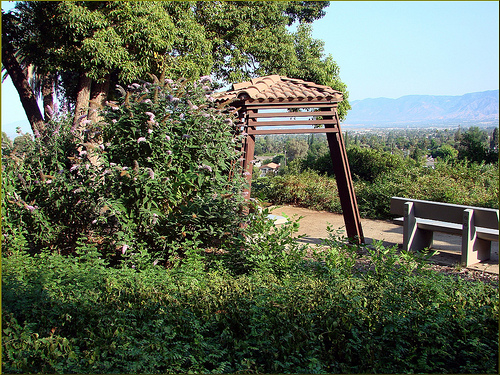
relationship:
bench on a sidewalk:
[379, 184, 479, 260] [278, 204, 483, 282]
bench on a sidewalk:
[390, 196, 500, 267] [276, 207, 458, 265]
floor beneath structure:
[266, 205, 329, 242] [221, 70, 378, 243]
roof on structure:
[207, 75, 342, 108] [232, 98, 376, 243]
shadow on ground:
[297, 234, 464, 267] [268, 199, 387, 234]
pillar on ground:
[330, 131, 372, 240] [271, 197, 391, 247]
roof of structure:
[207, 75, 342, 108] [226, 111, 371, 233]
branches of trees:
[72, 39, 125, 81] [15, 154, 271, 255]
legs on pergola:
[230, 140, 377, 244] [206, 75, 368, 247]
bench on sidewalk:
[390, 196, 500, 267] [266, 203, 499, 278]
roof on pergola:
[207, 75, 342, 108] [206, 75, 368, 247]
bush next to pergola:
[1, 77, 305, 263] [206, 75, 368, 247]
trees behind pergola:
[1, 1, 349, 166] [206, 75, 368, 247]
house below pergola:
[256, 151, 286, 171] [206, 75, 368, 247]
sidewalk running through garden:
[267, 201, 499, 286] [0, 1, 499, 373]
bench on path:
[390, 196, 500, 267] [268, 204, 498, 284]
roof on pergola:
[207, 75, 342, 108] [206, 75, 365, 251]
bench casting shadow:
[390, 196, 500, 267] [297, 234, 464, 267]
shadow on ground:
[297, 234, 464, 267] [267, 199, 499, 284]